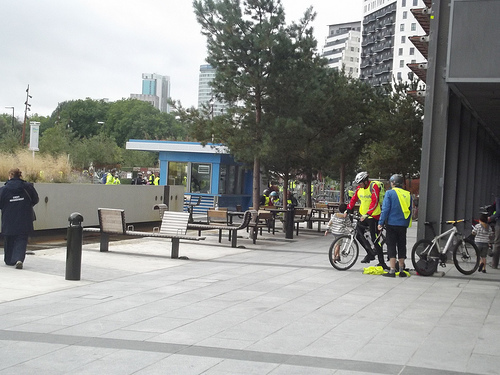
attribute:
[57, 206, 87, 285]
pole — black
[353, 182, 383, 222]
jersey — yellow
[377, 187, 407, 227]
jacket — blue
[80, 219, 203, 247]
benches — wooden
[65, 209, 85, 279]
pole — short, black, metal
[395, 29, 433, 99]
building — large, white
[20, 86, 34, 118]
poles — tall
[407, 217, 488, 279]
bicycle — white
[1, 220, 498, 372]
pavement — light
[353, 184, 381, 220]
vest — bright yellow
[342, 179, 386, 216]
jacket — long sleeved, red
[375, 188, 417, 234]
jacket — long sleeved, blue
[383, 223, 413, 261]
pants — dark, capri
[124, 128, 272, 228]
building — little, blue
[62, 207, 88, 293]
pole — dark, metal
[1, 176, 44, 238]
jacket — dark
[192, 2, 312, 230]
tree — pine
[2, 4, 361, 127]
sky — gray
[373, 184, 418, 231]
top — blue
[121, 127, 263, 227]
cabin — blue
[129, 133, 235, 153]
roof — white, blue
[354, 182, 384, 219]
vest — yellow